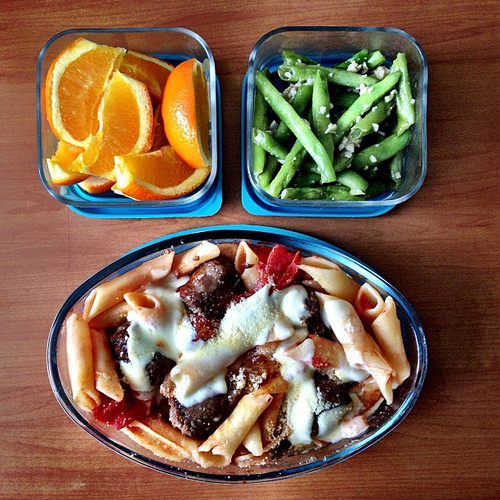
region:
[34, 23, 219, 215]
Orange slices in a container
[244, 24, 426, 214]
Beans in a container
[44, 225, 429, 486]
Pasta in a container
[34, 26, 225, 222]
Orange slices in a rectangular dish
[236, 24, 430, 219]
Beans in a rectangular dish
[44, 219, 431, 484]
Pasta with sauce in an oval dish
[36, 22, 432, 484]
Pasta, beans, and orange slices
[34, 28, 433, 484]
Orange wedges, green beans and pasta in separate dishes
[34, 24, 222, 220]
Orange cut into wedges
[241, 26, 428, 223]
Green beans in a clear container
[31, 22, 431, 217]
Two square bowls on the table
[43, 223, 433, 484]
One oval shaped bowl on the table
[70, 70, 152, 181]
An orange slice in the bowl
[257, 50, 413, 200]
Green beans in a bowl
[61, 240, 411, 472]
Pasta in a bowl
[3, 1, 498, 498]
The table is made of wood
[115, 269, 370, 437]
White sauce on the pasta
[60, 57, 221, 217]
Blue lid underneath the bowl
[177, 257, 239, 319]
A piece of sausage in the pasta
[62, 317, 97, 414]
Tube pasta in the oval bowl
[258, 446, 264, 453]
A group of red and white stop signs.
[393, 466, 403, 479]
A group of red and white stop signs.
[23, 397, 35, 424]
A group of red and white stop signs.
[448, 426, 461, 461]
A group of red and white stop signs.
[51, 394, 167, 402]
A group of red and white stop signs.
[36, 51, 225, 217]
blue lid under a container of oranges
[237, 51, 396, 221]
blue lid under a container of green beans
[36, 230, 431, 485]
pasta in an oval container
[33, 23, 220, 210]
oranges in a square container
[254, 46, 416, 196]
beans in a square container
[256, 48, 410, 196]
green beans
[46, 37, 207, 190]
orange cut into wedges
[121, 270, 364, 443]
white sauce on pasta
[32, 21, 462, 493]
three food containers on a wood table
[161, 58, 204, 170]
shiny orange peel on orange wedges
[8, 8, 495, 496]
a table has containers of food on top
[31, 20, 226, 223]
a blue container is sitting on its lid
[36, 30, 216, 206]
sliced oranges are in the container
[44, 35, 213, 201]
the oranges have their skins on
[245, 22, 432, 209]
green beans are cut in the container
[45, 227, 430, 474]
the main dish has ziti pasta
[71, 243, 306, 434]
pepperoni is in the dish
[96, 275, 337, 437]
black olives and tomato bits are in the pasta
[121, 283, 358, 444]
mozzarella cheese is melted in the pasta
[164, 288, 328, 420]
grated parmigiano cheese in on the pasta